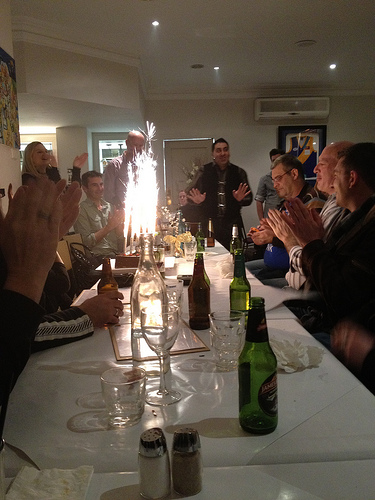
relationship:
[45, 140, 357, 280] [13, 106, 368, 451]
people are at party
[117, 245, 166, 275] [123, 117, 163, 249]
cake has sparklers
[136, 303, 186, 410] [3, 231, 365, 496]
wine glass on table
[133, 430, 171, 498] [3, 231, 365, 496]
salt shaker on table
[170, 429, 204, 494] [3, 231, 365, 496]
pepper shaker on table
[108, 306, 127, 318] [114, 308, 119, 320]
finger has ring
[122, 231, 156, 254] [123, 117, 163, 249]
candles have sparklers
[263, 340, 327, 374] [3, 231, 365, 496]
napkin on table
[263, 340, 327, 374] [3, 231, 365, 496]
napkin at end of table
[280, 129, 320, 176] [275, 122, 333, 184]
jersey in picture frame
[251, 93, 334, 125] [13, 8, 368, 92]
ac unit near ceiling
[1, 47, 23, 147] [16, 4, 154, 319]
picture on left hand side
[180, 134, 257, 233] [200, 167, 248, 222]
man wears vest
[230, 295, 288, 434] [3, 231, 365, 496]
glass bottle on table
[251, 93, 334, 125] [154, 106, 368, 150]
ac unit on wall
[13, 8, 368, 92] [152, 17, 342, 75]
ceiling has lights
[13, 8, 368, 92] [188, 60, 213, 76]
ceiling has speaker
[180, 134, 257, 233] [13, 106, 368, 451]
man at party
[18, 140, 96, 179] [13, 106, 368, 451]
woman at party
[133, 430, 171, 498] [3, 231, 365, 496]
salt shaker from table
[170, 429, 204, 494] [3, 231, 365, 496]
pepper shaker from table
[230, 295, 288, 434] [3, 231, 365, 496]
glass bottle from table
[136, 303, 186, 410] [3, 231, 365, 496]
wine glass from table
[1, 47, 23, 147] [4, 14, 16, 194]
picture from wall